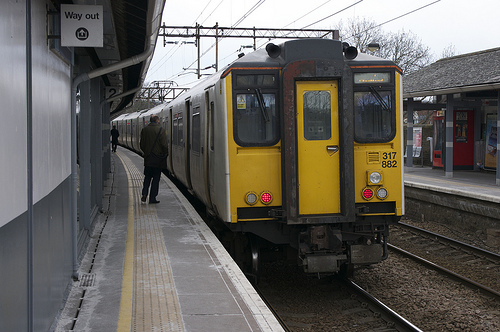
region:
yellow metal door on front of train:
[290, 77, 350, 235]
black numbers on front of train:
[381, 150, 401, 175]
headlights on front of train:
[238, 187, 275, 207]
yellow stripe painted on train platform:
[107, 237, 140, 321]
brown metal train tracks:
[410, 227, 475, 295]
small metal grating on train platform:
[70, 268, 110, 295]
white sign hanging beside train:
[53, 2, 110, 52]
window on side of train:
[180, 102, 208, 155]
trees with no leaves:
[346, 10, 430, 73]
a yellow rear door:
[230, 68, 405, 223]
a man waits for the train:
[141, 104, 170, 211]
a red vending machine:
[434, 108, 479, 167]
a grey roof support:
[443, 96, 454, 176]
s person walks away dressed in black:
[111, 119, 122, 156]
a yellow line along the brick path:
[113, 146, 136, 330]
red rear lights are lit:
[260, 186, 371, 203]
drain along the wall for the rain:
[66, 172, 121, 330]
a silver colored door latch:
[323, 144, 343, 154]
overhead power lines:
[153, 0, 445, 42]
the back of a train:
[215, 45, 407, 243]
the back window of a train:
[225, 68, 275, 159]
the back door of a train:
[280, 62, 357, 209]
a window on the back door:
[287, 78, 339, 150]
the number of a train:
[382, 136, 402, 174]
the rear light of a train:
[355, 169, 390, 189]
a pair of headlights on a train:
[358, 188, 398, 212]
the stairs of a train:
[275, 232, 352, 274]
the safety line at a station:
[121, 228, 195, 289]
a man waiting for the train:
[138, 115, 173, 206]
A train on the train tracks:
[100, 27, 421, 290]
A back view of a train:
[214, 37, 414, 229]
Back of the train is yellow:
[219, 64, 409, 225]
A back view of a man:
[126, 100, 177, 210]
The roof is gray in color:
[398, 40, 498, 108]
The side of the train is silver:
[106, 62, 224, 238]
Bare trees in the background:
[311, 10, 450, 82]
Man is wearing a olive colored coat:
[131, 118, 171, 167]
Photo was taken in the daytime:
[3, 4, 493, 330]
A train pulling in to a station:
[110, 26, 412, 281]